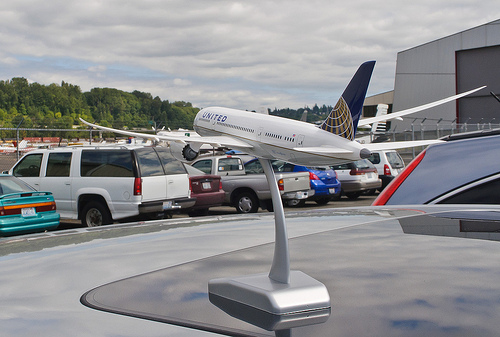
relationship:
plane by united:
[181, 72, 384, 170] [200, 108, 235, 125]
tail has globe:
[323, 48, 373, 138] [326, 93, 352, 142]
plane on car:
[181, 72, 384, 170] [51, 199, 495, 333]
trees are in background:
[6, 84, 168, 128] [1, 3, 459, 189]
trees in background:
[6, 84, 168, 128] [1, 3, 459, 189]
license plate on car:
[329, 188, 337, 194] [261, 159, 361, 196]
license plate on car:
[14, 207, 40, 222] [5, 169, 63, 238]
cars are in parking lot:
[17, 164, 120, 204] [5, 139, 492, 261]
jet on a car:
[181, 72, 384, 170] [51, 199, 495, 333]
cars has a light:
[0, 146, 196, 228] [130, 170, 144, 201]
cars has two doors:
[0, 146, 196, 228] [133, 146, 196, 210]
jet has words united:
[181, 72, 384, 170] [200, 108, 235, 125]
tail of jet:
[323, 48, 373, 138] [181, 72, 384, 170]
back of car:
[3, 196, 61, 229] [5, 169, 63, 238]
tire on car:
[291, 197, 301, 208] [261, 159, 361, 196]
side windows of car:
[262, 161, 301, 174] [261, 159, 361, 196]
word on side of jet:
[193, 101, 236, 125] [181, 72, 384, 170]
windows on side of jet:
[213, 115, 256, 138] [181, 72, 384, 170]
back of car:
[304, 170, 345, 197] [261, 159, 361, 196]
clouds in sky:
[141, 14, 164, 42] [15, 6, 444, 93]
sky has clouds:
[15, 6, 444, 93] [141, 14, 164, 42]